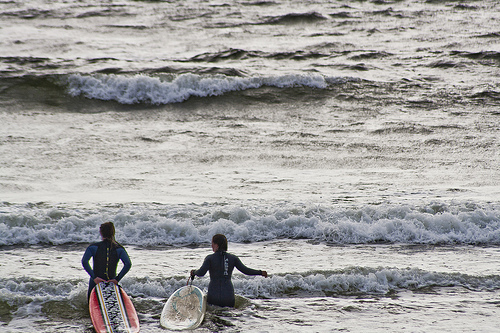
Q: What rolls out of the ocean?
A: Waves.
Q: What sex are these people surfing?
A: Female.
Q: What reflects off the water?
A: Sun.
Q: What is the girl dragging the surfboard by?
A: Rope.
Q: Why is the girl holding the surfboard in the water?
A: To use it.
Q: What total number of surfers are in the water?
A: 2.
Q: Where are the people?
A: In the ocean.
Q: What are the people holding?
A: Boogie boards.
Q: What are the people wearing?
A: Wet suits.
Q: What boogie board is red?
A: The one on the left.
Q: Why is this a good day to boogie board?
A: Big waves.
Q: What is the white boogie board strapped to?
A: The woman's wrist.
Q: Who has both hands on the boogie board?
A: The woman on the left.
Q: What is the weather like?
A: Overcast.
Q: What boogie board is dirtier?
A: The one on the right.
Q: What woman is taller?
A: The one on the left.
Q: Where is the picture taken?
A: A beach.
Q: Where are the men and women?
A: In the ocean.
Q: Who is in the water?
A: Surfers.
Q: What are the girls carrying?
A: Surfboards.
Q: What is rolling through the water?
A: Waves.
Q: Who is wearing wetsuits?
A: Surfers.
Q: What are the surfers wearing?
A: Wetsuits.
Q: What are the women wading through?
A: The water.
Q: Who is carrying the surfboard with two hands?
A: Woman on the left.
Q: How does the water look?
A: Grey and choppy.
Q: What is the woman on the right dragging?
A: Surfboard.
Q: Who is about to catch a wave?
A: The surfers.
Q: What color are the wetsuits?
A: Blue.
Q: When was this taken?
A: Daytime.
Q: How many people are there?
A: 2.